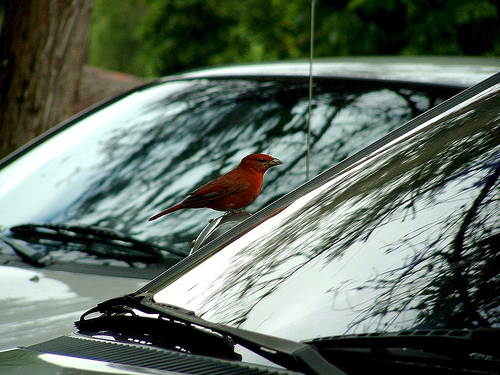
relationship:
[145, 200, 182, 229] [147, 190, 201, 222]
feathers on feathers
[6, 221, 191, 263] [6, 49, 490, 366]
wiper laying on front of car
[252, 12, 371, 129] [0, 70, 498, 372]
antennae sticking out of car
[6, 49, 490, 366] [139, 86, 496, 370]
car has windscreen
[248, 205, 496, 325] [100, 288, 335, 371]
window has wiper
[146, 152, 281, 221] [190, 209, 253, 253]
bird perched on side mirror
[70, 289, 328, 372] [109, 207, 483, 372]
slits front car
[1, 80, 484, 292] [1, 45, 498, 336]
window front car